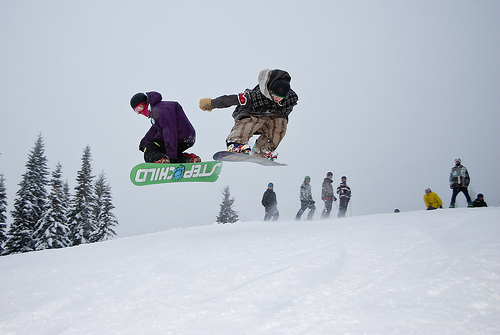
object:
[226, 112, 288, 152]
plaid pants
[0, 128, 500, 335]
snow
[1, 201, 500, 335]
slopes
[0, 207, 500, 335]
ground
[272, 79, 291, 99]
hat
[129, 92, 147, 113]
hat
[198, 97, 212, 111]
gloves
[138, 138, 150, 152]
gloves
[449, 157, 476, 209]
man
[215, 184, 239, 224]
pine tree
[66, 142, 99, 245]
pine tree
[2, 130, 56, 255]
pine tree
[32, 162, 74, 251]
pine tree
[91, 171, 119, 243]
pine tree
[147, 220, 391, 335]
tracks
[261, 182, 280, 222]
man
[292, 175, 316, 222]
man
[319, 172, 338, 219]
man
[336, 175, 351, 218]
man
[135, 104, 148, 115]
glasses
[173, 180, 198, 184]
board edge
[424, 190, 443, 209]
coat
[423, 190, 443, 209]
snow jacket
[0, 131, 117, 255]
leaves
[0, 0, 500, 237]
sky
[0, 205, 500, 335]
hill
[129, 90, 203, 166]
man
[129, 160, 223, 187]
snowboard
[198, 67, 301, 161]
man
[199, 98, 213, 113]
hand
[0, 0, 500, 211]
wind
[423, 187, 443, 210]
man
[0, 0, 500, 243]
air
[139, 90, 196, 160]
jacket